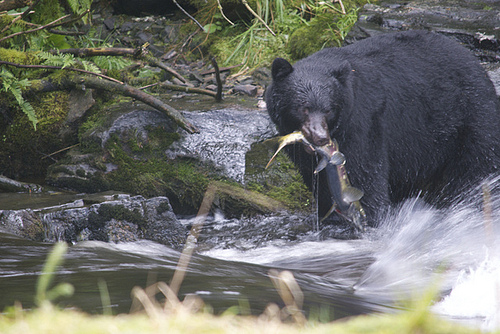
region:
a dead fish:
[271, 121, 372, 233]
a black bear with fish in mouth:
[248, 59, 353, 165]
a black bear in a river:
[250, 13, 494, 265]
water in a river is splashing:
[85, 170, 477, 304]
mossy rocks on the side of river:
[25, 40, 251, 249]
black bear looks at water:
[272, 65, 344, 146]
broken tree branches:
[10, 54, 195, 134]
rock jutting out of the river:
[8, 180, 189, 265]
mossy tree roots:
[178, 11, 368, 72]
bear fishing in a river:
[3, 2, 498, 308]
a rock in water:
[33, 189, 188, 269]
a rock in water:
[84, 92, 257, 221]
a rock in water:
[228, 77, 255, 96]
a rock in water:
[131, 24, 153, 41]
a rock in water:
[143, 32, 158, 57]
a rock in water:
[87, 15, 112, 38]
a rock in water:
[8, 78, 98, 143]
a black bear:
[236, 24, 496, 246]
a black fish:
[271, 125, 378, 230]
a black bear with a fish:
[258, 32, 498, 261]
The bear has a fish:
[235, 107, 397, 237]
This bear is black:
[266, 56, 449, 268]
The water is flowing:
[83, 94, 360, 329]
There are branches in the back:
[20, 8, 244, 180]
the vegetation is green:
[221, 10, 405, 103]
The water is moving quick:
[371, 185, 498, 317]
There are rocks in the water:
[27, 165, 266, 303]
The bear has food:
[273, 44, 468, 331]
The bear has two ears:
[255, 61, 389, 154]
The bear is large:
[230, 53, 455, 255]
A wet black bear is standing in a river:
[241, 15, 479, 232]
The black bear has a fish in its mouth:
[279, 29, 464, 246]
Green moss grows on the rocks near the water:
[75, 99, 313, 239]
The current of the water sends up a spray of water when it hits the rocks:
[296, 159, 491, 306]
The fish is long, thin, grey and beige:
[290, 106, 375, 245]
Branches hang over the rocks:
[6, 53, 247, 157]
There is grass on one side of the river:
[21, 255, 478, 323]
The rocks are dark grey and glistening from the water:
[34, 74, 307, 227]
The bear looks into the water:
[244, 24, 497, 219]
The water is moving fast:
[26, 207, 481, 297]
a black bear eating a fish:
[260, 18, 496, 244]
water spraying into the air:
[406, 194, 478, 251]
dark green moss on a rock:
[74, 195, 139, 227]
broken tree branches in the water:
[89, 40, 200, 121]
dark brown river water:
[99, 254, 131, 287]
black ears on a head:
[274, 54, 362, 81]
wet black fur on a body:
[402, 74, 454, 125]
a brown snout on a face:
[303, 109, 336, 149]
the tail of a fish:
[260, 132, 310, 168]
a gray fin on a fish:
[311, 162, 332, 174]